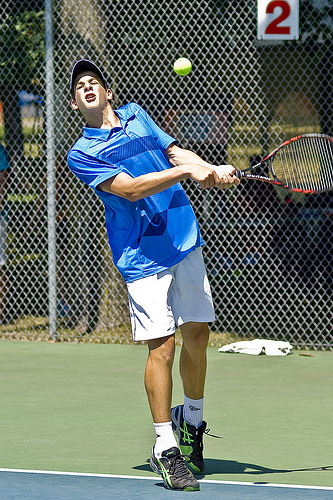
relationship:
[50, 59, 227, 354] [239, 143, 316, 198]
man holding tennis racket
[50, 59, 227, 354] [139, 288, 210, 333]
man wearing shorts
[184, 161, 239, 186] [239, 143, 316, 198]
hands are on tennis racket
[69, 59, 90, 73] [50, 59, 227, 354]
cap on man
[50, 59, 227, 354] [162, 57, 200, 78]
man hitting tennis ball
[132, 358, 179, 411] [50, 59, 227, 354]
leg of man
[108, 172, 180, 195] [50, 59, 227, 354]
arm of man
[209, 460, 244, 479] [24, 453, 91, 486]
shadow on ground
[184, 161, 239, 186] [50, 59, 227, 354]
hands of man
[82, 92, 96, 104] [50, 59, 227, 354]
mouth of man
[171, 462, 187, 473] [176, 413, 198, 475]
lace on shoes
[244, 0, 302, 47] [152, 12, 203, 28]
number on fence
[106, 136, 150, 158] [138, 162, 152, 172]
stripe on shirt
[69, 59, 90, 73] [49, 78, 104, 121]
cap on head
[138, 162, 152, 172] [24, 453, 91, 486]
shirt on ground